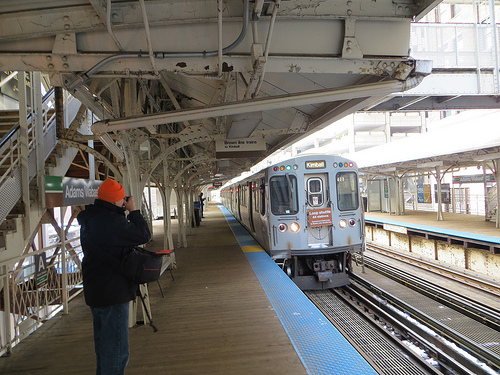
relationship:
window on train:
[270, 174, 301, 215] [219, 155, 366, 292]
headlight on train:
[289, 221, 300, 233] [219, 155, 366, 292]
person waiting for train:
[78, 177, 155, 374] [219, 155, 366, 292]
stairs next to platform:
[2, 71, 91, 301] [0, 204, 378, 374]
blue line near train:
[218, 200, 377, 374] [219, 155, 366, 292]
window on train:
[336, 171, 359, 211] [219, 155, 366, 292]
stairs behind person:
[2, 71, 91, 301] [78, 177, 155, 374]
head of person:
[257, 184, 267, 197] [258, 185, 266, 197]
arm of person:
[105, 194, 152, 257] [78, 177, 155, 374]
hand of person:
[123, 195, 136, 214] [78, 177, 155, 374]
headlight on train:
[340, 219, 349, 229] [219, 155, 366, 292]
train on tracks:
[219, 155, 366, 292] [302, 267, 499, 374]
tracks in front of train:
[302, 267, 499, 374] [219, 155, 366, 292]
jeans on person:
[89, 302, 131, 374] [78, 177, 155, 374]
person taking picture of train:
[78, 177, 155, 374] [219, 155, 366, 292]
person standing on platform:
[198, 193, 209, 220] [0, 204, 378, 374]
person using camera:
[78, 177, 155, 374] [120, 194, 133, 210]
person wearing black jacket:
[78, 177, 155, 374] [74, 199, 156, 307]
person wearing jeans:
[78, 177, 155, 374] [89, 302, 131, 374]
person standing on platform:
[78, 177, 155, 374] [0, 204, 378, 374]